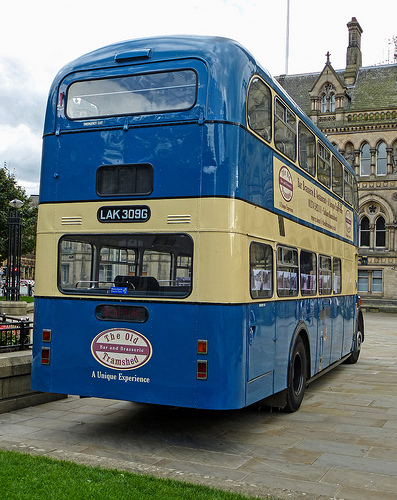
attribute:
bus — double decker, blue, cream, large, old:
[27, 32, 365, 409]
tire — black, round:
[266, 327, 308, 415]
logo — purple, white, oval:
[89, 325, 153, 372]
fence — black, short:
[0, 311, 34, 356]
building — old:
[269, 12, 396, 317]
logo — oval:
[277, 162, 297, 204]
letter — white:
[97, 208, 108, 222]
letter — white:
[104, 206, 116, 222]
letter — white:
[111, 207, 122, 223]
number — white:
[119, 208, 129, 221]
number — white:
[126, 208, 137, 222]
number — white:
[132, 206, 142, 222]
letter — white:
[140, 207, 151, 223]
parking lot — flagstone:
[1, 307, 396, 497]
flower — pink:
[0, 321, 12, 335]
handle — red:
[56, 89, 66, 110]